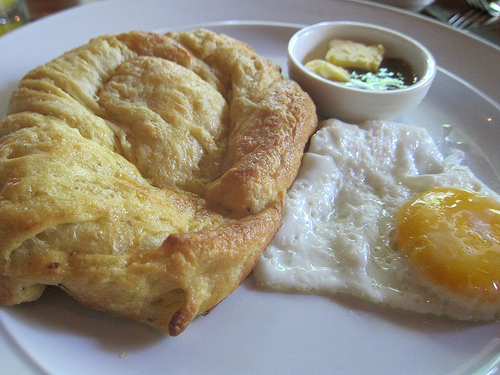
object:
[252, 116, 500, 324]
egg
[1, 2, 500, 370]
plate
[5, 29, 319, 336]
danish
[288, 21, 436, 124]
cup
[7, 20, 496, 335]
food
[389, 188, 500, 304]
yolk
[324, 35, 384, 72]
butter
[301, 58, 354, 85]
butter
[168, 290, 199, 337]
part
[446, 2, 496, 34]
fork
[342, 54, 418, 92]
syrup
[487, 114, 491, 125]
reflection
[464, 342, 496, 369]
reflection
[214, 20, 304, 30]
reflection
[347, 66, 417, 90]
reflection